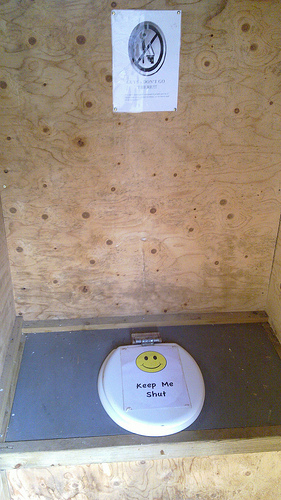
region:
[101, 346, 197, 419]
this is a toilet sink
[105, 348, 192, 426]
the lid is closed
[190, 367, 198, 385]
the lid id white in color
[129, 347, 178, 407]
the lid has white paper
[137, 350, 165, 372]
the face is yellow in color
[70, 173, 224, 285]
the wall is wooden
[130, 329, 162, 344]
this is a twist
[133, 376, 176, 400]
it is written keep me shut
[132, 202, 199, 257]
the wall is brown in color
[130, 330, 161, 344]
the twist is metallic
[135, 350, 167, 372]
Yellow smiley face with black eyes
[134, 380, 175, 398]
Black text on white paper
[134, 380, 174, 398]
Text reading Keep Me Shut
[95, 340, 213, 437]
White oval toilet seat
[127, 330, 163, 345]
Rusty silver hinge on toilet lid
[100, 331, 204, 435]
White sign on closed toilet lid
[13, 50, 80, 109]
Wood grain marks on wall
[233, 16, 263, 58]
Brown circles on wooden wall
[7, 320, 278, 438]
Dark gray rectangular seat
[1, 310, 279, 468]
Light wooden frame around toilet seat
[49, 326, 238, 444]
A white toilet lid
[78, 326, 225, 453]
a closed toilet lid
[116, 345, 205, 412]
a sign on a toilet lid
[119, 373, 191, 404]
black letters on a white sign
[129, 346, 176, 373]
a yellow Smiley Face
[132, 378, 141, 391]
A black letter "K"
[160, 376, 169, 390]
A black letter "M"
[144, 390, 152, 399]
A black letter "S"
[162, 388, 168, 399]
A black letter "t"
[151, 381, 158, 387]
A black letter "p"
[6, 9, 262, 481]
inside of an outhouse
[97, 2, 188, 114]
black and white sign on wall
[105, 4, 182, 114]
notice of what is not allowed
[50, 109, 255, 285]
wooden wall filled with knotholes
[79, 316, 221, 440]
closed toilet seat set in panel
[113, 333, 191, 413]
smiley-face sign with instruction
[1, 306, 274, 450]
wooden strips used to frame toilet panel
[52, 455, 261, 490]
swirling darker grain of wood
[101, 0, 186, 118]
four tacks in each corner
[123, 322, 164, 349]
hinge connecting lid and toilet seat to panel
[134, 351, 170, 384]
Yellow face on lid.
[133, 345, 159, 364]
Face has black eyes.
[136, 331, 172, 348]
Silver hinge on toilet seat.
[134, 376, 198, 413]
Sign has black writing on it.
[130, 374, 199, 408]
Sign says keep me shut.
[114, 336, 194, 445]
White piece of paper on toilet seat.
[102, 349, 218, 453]
Toilet seat is white.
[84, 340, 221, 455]
Toilet seat is attached to wood seat.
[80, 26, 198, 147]
White sign tacked to back wall.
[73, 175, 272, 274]
Wood surrounding toilet area.